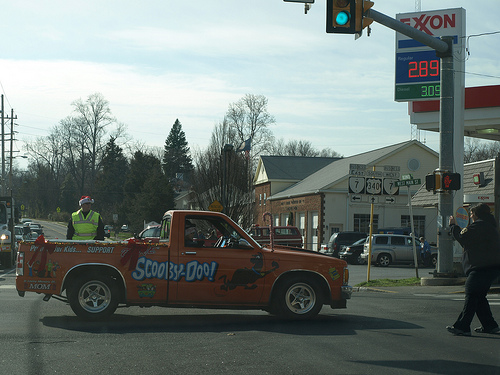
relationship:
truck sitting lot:
[13, 208, 350, 315] [290, 213, 490, 321]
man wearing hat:
[66, 191, 114, 250] [79, 196, 95, 206]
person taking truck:
[445, 204, 500, 338] [29, 194, 365, 306]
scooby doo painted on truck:
[215, 250, 281, 293] [1, 204, 370, 337]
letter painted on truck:
[131, 256, 218, 283] [1, 204, 370, 337]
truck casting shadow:
[14, 208, 350, 318] [39, 307, 427, 337]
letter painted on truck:
[131, 256, 218, 283] [14, 208, 350, 318]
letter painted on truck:
[142, 259, 152, 279] [14, 208, 350, 318]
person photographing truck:
[440, 202, 499, 343] [10, 208, 358, 334]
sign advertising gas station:
[389, 5, 468, 107] [387, 5, 499, 286]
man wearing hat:
[66, 196, 105, 242] [77, 184, 94, 204]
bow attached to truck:
[24, 247, 52, 273] [14, 208, 350, 318]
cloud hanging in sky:
[0, 0, 500, 169] [3, 3, 488, 146]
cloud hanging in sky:
[0, 0, 500, 169] [2, 1, 483, 171]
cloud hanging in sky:
[2, 59, 351, 117] [2, 1, 483, 171]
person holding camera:
[445, 204, 500, 338] [436, 209, 459, 236]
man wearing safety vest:
[66, 196, 105, 242] [68, 206, 102, 241]